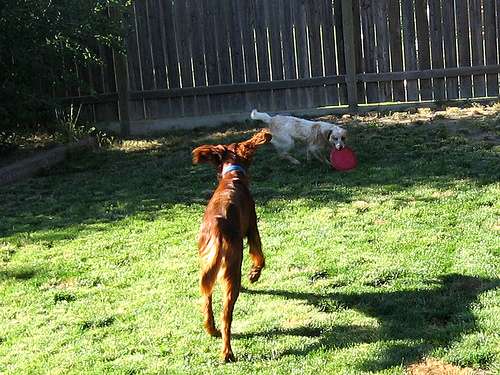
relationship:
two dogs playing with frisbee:
[183, 95, 374, 367] [331, 148, 356, 169]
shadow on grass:
[325, 270, 478, 373] [288, 213, 444, 286]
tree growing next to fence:
[9, 5, 109, 112] [135, 5, 486, 102]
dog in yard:
[245, 101, 361, 167] [21, 89, 488, 374]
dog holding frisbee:
[245, 101, 361, 167] [331, 148, 356, 169]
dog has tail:
[245, 101, 361, 167] [246, 103, 271, 127]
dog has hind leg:
[245, 101, 361, 167] [279, 141, 304, 169]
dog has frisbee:
[245, 101, 361, 167] [331, 148, 356, 169]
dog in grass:
[245, 101, 361, 167] [288, 213, 444, 286]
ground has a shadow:
[327, 209, 431, 258] [325, 270, 478, 373]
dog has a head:
[245, 101, 361, 167] [324, 125, 349, 152]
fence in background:
[135, 5, 486, 102] [59, 20, 124, 44]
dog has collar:
[189, 124, 273, 361] [220, 160, 254, 177]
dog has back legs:
[245, 101, 361, 167] [193, 274, 240, 365]